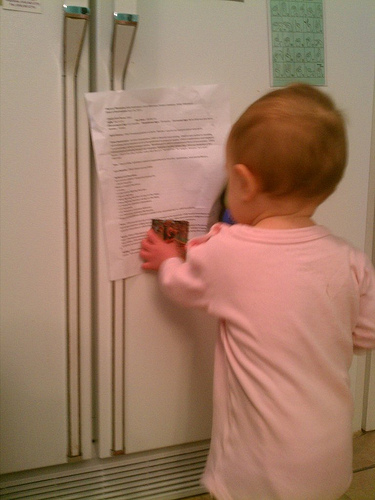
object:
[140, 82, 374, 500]
baby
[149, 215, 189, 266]
picture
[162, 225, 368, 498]
gown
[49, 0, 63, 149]
wall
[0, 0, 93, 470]
door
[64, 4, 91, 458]
handles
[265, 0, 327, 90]
calendar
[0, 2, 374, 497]
refrigerator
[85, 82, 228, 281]
paper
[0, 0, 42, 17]
writing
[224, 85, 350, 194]
hair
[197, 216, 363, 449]
outfit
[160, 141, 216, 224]
magnet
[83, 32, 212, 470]
fridge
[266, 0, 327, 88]
poster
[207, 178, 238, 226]
pacifier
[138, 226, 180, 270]
hands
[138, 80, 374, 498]
child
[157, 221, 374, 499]
shirt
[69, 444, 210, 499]
vents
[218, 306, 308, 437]
wrinkles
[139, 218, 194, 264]
pictures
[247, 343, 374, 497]
walls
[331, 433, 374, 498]
floor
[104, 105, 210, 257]
letters